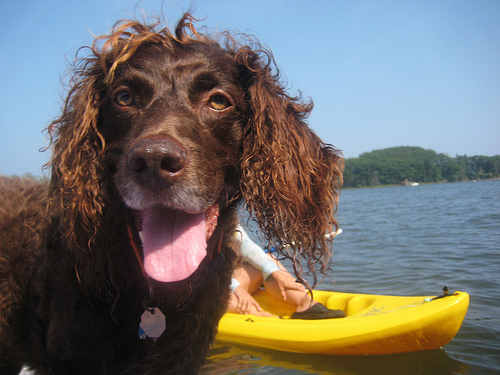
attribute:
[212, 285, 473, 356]
boat — yellow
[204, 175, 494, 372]
water body — large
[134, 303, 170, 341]
symbol — silver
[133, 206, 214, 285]
tongue — orange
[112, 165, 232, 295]
tongue — pink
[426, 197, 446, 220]
water — blue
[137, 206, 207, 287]
tongue — pink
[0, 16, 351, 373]
dog — brown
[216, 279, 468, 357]
kayak — yellow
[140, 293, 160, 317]
loop — small, metal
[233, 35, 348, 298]
ear — furry, black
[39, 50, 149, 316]
ear — furry, black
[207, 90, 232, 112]
eye — black, yellow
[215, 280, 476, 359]
canoe — yellow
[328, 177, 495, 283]
water — calm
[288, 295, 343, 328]
shoes — black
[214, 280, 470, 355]
raft — yellow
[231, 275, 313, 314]
legs — lower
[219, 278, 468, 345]
boat — motor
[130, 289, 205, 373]
tag — silver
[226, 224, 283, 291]
shirt — white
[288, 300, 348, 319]
wear — black, foot